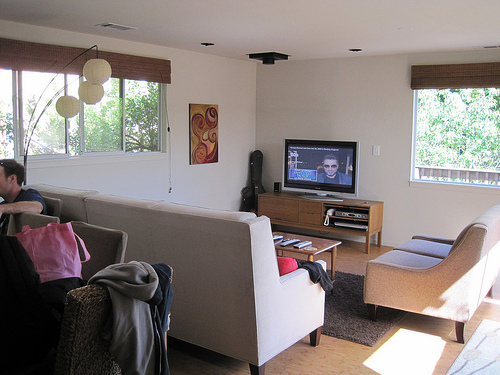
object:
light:
[81, 57, 112, 86]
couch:
[21, 180, 328, 374]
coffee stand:
[271, 231, 344, 297]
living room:
[0, 0, 500, 375]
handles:
[72, 230, 92, 263]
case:
[240, 149, 267, 213]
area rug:
[319, 266, 407, 346]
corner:
[236, 60, 275, 214]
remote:
[293, 240, 313, 249]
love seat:
[362, 203, 498, 346]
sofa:
[83, 191, 328, 375]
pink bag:
[14, 219, 91, 285]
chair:
[38, 219, 130, 282]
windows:
[0, 38, 173, 167]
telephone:
[323, 208, 336, 226]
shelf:
[257, 190, 385, 237]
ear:
[10, 174, 16, 183]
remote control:
[279, 238, 300, 247]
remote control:
[273, 235, 284, 240]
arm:
[2, 191, 45, 214]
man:
[0, 157, 47, 220]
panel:
[372, 145, 381, 155]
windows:
[408, 60, 500, 195]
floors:
[326, 358, 353, 373]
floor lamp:
[53, 43, 113, 119]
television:
[280, 137, 362, 203]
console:
[257, 189, 384, 254]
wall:
[255, 47, 500, 256]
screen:
[283, 138, 357, 194]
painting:
[188, 102, 220, 166]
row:
[0, 68, 167, 163]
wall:
[0, 18, 258, 212]